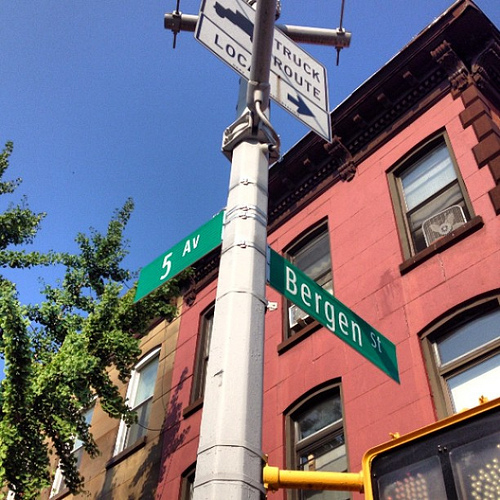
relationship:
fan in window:
[421, 202, 466, 247] [397, 137, 468, 255]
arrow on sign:
[287, 92, 314, 118] [193, 1, 332, 144]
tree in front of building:
[0, 139, 196, 500] [1, 286, 184, 500]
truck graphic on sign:
[213, 2, 255, 42] [193, 1, 332, 144]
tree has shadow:
[0, 139, 196, 500] [94, 369, 190, 500]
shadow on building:
[94, 369, 190, 500] [154, 1, 500, 499]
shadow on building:
[94, 369, 190, 500] [1, 286, 184, 500]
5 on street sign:
[159, 253, 173, 280] [131, 210, 225, 300]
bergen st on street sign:
[286, 266, 383, 352] [266, 245, 400, 384]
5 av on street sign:
[159, 236, 201, 280] [131, 210, 225, 300]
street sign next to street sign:
[131, 210, 225, 300] [266, 245, 400, 384]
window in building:
[282, 224, 336, 334] [154, 1, 500, 499]